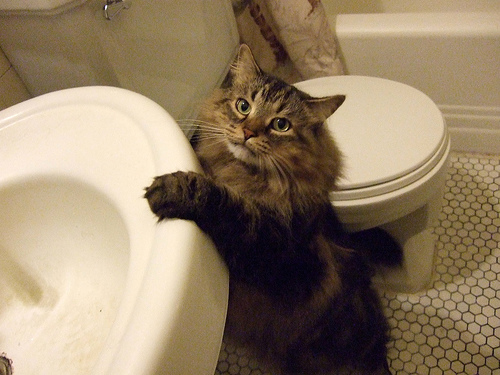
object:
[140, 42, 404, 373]
cat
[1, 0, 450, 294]
toilet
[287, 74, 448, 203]
seat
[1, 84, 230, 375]
sink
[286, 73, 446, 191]
cover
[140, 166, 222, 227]
paw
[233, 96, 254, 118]
eye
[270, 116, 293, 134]
eye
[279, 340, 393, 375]
back legs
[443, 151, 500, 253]
tile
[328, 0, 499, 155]
bathtub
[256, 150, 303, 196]
whiskers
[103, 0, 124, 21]
flush handle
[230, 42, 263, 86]
ear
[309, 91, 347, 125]
ear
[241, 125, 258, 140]
nose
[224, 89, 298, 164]
face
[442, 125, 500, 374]
floor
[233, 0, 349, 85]
shower curtain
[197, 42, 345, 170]
head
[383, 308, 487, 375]
shadow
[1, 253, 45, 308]
shadow